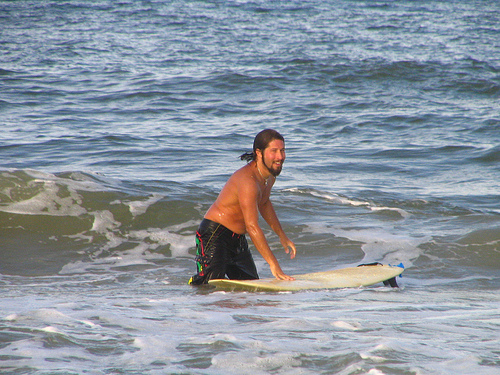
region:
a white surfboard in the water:
[208, 258, 403, 296]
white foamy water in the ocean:
[2, 150, 497, 373]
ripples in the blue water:
[2, 2, 498, 197]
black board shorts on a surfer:
[187, 216, 254, 291]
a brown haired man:
[241, 122, 298, 174]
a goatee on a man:
[257, 150, 286, 181]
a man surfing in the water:
[188, 123, 400, 305]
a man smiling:
[242, 124, 298, 184]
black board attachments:
[367, 259, 406, 298]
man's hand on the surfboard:
[242, 241, 321, 301]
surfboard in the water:
[257, 257, 331, 311]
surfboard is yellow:
[285, 271, 332, 290]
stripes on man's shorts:
[185, 240, 228, 263]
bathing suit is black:
[217, 227, 237, 258]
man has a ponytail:
[220, 141, 262, 171]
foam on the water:
[145, 288, 166, 328]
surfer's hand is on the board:
[253, 242, 315, 298]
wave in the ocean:
[37, 171, 92, 213]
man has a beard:
[267, 164, 281, 174]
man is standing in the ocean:
[165, 276, 236, 304]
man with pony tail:
[187, 123, 302, 300]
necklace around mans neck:
[239, 155, 286, 197]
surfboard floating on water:
[206, 259, 406, 306]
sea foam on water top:
[10, 163, 165, 253]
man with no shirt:
[181, 126, 305, 294]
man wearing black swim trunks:
[176, 125, 297, 296]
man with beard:
[252, 132, 297, 179]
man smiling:
[241, 122, 308, 183]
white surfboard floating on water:
[201, 250, 431, 305]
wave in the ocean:
[0, 127, 170, 263]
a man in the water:
[105, 73, 432, 339]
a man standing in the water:
[139, 100, 424, 360]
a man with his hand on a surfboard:
[194, 96, 449, 362]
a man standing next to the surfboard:
[148, 81, 429, 372]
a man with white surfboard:
[155, 76, 414, 373]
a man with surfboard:
[148, 33, 475, 355]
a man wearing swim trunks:
[69, 32, 425, 369]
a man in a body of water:
[39, 4, 459, 372]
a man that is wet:
[104, 50, 481, 373]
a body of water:
[35, 40, 496, 348]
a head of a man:
[243, 120, 288, 175]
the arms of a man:
[242, 205, 281, 266]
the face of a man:
[266, 141, 286, 168]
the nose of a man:
[272, 150, 287, 162]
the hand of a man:
[269, 264, 297, 285]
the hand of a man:
[282, 236, 299, 260]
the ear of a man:
[253, 145, 263, 159]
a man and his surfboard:
[186, 122, 410, 298]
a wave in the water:
[38, 164, 142, 267]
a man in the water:
[180, 117, 299, 301]